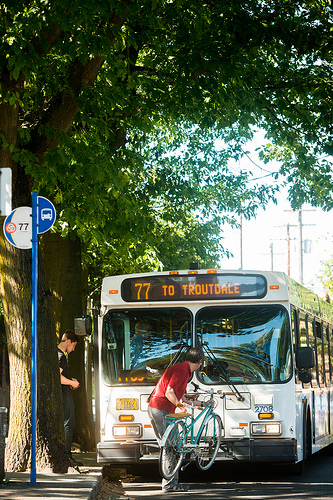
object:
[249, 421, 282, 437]
headlights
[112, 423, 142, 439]
headlight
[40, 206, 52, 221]
sign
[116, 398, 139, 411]
license plate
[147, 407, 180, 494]
pants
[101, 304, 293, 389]
bus windows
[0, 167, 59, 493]
bus stop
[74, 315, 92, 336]
mirror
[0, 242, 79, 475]
tree trunk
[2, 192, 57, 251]
bus signs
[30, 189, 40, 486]
pole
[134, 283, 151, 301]
number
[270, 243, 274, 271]
pole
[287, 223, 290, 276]
pole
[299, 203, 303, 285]
pole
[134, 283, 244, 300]
sign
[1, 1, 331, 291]
green leaves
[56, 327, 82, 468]
man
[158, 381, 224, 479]
bicycle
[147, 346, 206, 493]
man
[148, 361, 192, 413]
red shirt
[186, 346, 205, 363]
hair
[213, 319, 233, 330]
light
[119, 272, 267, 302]
direction light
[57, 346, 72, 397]
shirt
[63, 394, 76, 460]
pants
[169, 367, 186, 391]
sleeve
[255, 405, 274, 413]
id number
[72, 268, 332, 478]
bus